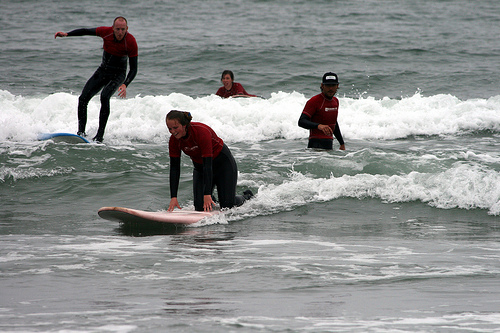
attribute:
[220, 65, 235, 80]
hair — brown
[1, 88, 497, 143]
sea foam — white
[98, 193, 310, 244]
surfboard — red and black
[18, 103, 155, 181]
wave — small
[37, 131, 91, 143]
surfboard — blue and white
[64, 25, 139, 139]
wet suit — black and red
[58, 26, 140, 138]
surf suit — red and black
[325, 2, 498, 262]
waves — light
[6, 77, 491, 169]
wave — small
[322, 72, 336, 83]
design — white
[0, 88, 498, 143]
waves — large, white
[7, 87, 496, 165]
foam — white